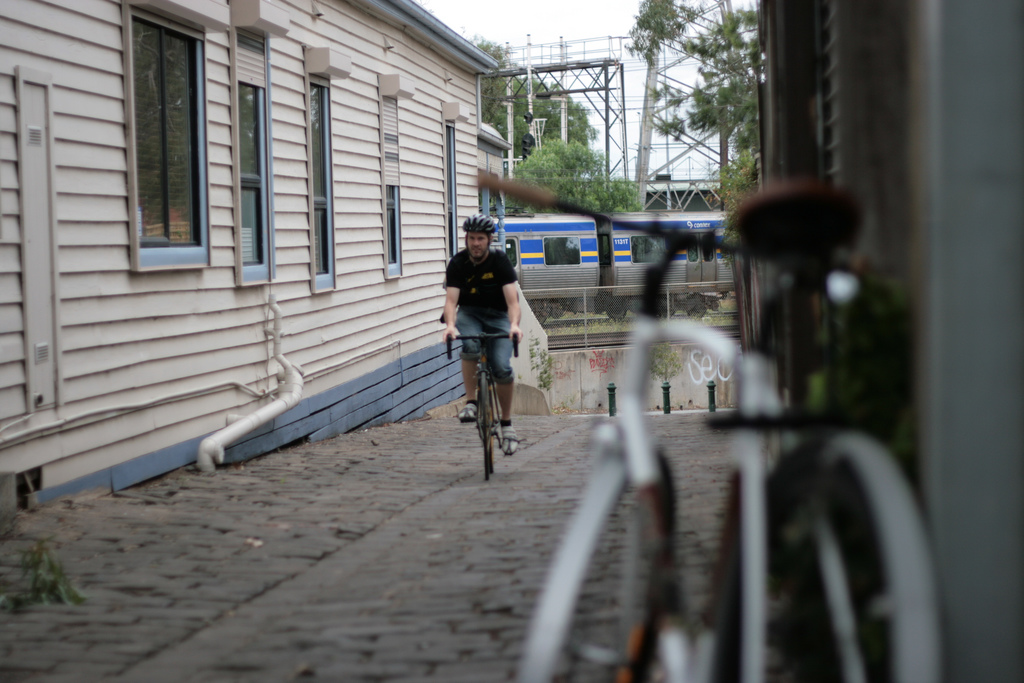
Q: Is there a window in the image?
A: Yes, there is a window.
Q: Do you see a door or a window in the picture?
A: Yes, there is a window.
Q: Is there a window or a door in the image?
A: Yes, there is a window.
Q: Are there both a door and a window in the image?
A: No, there is a window but no doors.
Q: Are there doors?
A: No, there are no doors.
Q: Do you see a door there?
A: No, there are no doors.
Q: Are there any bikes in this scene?
A: Yes, there is a bike.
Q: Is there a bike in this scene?
A: Yes, there is a bike.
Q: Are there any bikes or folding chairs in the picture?
A: Yes, there is a bike.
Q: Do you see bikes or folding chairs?
A: Yes, there is a bike.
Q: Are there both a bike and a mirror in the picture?
A: No, there is a bike but no mirrors.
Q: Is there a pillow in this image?
A: No, there are no pillows.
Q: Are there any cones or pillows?
A: No, there are no pillows or cones.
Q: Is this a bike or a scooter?
A: This is a bike.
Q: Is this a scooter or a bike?
A: This is a bike.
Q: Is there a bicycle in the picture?
A: Yes, there is a bicycle.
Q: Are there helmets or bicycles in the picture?
A: Yes, there is a bicycle.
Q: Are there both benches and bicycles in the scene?
A: No, there is a bicycle but no benches.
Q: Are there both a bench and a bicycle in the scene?
A: No, there is a bicycle but no benches.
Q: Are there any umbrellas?
A: No, there are no umbrellas.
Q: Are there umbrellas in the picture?
A: No, there are no umbrellas.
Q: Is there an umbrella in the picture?
A: No, there are no umbrellas.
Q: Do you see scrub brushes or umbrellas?
A: No, there are no umbrellas or scrub brushes.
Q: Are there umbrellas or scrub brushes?
A: No, there are no umbrellas or scrub brushes.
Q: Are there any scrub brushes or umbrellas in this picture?
A: No, there are no umbrellas or scrub brushes.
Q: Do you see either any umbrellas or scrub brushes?
A: No, there are no umbrellas or scrub brushes.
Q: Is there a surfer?
A: No, there are no surfers.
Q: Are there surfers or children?
A: No, there are no surfers or children.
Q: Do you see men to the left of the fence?
A: Yes, there is a man to the left of the fence.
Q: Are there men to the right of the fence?
A: No, the man is to the left of the fence.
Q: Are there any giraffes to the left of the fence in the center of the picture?
A: No, there is a man to the left of the fence.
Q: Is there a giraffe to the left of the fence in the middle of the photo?
A: No, there is a man to the left of the fence.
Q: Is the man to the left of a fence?
A: Yes, the man is to the left of a fence.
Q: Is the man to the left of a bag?
A: No, the man is to the left of a fence.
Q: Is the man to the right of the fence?
A: No, the man is to the left of the fence.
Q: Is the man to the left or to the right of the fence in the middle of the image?
A: The man is to the left of the fence.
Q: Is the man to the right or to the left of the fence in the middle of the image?
A: The man is to the left of the fence.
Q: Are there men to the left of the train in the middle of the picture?
A: Yes, there is a man to the left of the train.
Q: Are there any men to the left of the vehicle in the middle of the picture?
A: Yes, there is a man to the left of the train.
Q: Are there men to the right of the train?
A: No, the man is to the left of the train.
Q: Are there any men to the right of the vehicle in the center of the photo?
A: No, the man is to the left of the train.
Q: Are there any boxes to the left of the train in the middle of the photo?
A: No, there is a man to the left of the train.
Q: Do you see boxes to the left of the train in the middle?
A: No, there is a man to the left of the train.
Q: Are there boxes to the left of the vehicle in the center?
A: No, there is a man to the left of the train.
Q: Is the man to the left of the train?
A: Yes, the man is to the left of the train.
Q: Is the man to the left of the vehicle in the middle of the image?
A: Yes, the man is to the left of the train.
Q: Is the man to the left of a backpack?
A: No, the man is to the left of the train.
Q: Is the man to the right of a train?
A: No, the man is to the left of a train.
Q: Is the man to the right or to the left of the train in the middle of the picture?
A: The man is to the left of the train.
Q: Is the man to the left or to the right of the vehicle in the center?
A: The man is to the left of the train.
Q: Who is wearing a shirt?
A: The man is wearing a shirt.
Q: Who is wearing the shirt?
A: The man is wearing a shirt.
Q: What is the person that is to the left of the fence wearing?
A: The man is wearing a shirt.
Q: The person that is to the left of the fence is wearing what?
A: The man is wearing a shirt.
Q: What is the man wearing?
A: The man is wearing a shirt.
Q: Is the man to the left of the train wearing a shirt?
A: Yes, the man is wearing a shirt.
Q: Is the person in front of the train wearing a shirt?
A: Yes, the man is wearing a shirt.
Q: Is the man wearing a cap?
A: No, the man is wearing a shirt.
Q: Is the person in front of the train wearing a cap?
A: No, the man is wearing a shirt.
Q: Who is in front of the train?
A: The man is in front of the train.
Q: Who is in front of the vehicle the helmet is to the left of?
A: The man is in front of the train.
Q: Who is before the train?
A: The man is in front of the train.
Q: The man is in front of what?
A: The man is in front of the train.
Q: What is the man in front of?
A: The man is in front of the train.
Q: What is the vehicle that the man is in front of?
A: The vehicle is a train.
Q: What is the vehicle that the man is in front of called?
A: The vehicle is a train.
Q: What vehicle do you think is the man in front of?
A: The man is in front of the train.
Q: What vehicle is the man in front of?
A: The man is in front of the train.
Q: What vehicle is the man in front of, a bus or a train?
A: The man is in front of a train.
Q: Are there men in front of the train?
A: Yes, there is a man in front of the train.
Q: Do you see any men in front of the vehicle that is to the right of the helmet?
A: Yes, there is a man in front of the train.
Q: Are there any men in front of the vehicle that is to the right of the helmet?
A: Yes, there is a man in front of the train.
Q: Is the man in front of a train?
A: Yes, the man is in front of a train.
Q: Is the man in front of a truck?
A: No, the man is in front of a train.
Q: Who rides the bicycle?
A: The man rides the bicycle.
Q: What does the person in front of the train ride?
A: The man rides the bicycle.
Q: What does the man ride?
A: The man rides the bicycle.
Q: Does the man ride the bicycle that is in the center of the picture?
A: Yes, the man rides the bicycle.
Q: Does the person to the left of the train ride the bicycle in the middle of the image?
A: Yes, the man rides the bicycle.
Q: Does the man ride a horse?
A: No, the man rides the bicycle.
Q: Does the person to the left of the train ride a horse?
A: No, the man rides the bicycle.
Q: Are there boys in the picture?
A: No, there are no boys.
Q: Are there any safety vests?
A: No, there are no safety vests.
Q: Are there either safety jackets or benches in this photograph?
A: No, there are no safety jackets or benches.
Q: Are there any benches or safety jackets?
A: No, there are no safety jackets or benches.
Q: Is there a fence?
A: Yes, there is a fence.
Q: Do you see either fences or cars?
A: Yes, there is a fence.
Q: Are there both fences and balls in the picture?
A: No, there is a fence but no balls.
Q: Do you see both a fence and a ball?
A: No, there is a fence but no balls.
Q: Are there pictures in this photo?
A: No, there are no pictures.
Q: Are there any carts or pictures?
A: No, there are no pictures or carts.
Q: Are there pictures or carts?
A: No, there are no pictures or carts.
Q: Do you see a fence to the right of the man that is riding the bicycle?
A: Yes, there is a fence to the right of the man.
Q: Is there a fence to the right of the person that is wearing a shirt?
A: Yes, there is a fence to the right of the man.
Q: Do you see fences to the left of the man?
A: No, the fence is to the right of the man.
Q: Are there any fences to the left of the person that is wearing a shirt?
A: No, the fence is to the right of the man.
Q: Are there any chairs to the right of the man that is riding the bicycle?
A: No, there is a fence to the right of the man.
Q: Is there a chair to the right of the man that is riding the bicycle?
A: No, there is a fence to the right of the man.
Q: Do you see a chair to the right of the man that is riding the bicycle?
A: No, there is a fence to the right of the man.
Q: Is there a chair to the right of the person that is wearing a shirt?
A: No, there is a fence to the right of the man.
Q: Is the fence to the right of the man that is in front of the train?
A: Yes, the fence is to the right of the man.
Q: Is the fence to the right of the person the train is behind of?
A: Yes, the fence is to the right of the man.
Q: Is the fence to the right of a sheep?
A: No, the fence is to the right of the man.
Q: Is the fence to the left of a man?
A: No, the fence is to the right of a man.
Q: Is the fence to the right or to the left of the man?
A: The fence is to the right of the man.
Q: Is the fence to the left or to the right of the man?
A: The fence is to the right of the man.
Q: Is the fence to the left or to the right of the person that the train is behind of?
A: The fence is to the right of the man.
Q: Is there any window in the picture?
A: Yes, there are windows.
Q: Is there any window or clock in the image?
A: Yes, there are windows.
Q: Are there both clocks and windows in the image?
A: No, there are windows but no clocks.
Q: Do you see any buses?
A: No, there are no buses.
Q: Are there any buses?
A: No, there are no buses.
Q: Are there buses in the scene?
A: No, there are no buses.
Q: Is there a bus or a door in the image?
A: No, there are no buses or doors.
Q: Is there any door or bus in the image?
A: No, there are no buses or doors.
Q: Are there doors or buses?
A: No, there are no buses or doors.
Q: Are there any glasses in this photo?
A: No, there are no glasses.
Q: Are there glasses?
A: No, there are no glasses.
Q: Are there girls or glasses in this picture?
A: No, there are no glasses or girls.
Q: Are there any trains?
A: Yes, there is a train.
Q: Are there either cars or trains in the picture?
A: Yes, there is a train.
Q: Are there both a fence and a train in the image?
A: Yes, there are both a train and a fence.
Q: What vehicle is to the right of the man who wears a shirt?
A: The vehicle is a train.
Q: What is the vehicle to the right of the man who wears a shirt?
A: The vehicle is a train.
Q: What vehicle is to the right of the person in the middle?
A: The vehicle is a train.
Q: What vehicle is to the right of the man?
A: The vehicle is a train.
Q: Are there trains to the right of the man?
A: Yes, there is a train to the right of the man.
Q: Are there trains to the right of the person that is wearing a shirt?
A: Yes, there is a train to the right of the man.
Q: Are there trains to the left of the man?
A: No, the train is to the right of the man.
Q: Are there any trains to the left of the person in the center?
A: No, the train is to the right of the man.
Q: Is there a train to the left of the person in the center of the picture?
A: No, the train is to the right of the man.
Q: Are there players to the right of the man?
A: No, there is a train to the right of the man.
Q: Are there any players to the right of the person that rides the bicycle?
A: No, there is a train to the right of the man.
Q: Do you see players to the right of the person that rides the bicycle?
A: No, there is a train to the right of the man.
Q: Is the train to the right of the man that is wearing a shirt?
A: Yes, the train is to the right of the man.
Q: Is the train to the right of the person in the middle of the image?
A: Yes, the train is to the right of the man.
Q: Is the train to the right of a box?
A: No, the train is to the right of the man.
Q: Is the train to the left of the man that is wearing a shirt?
A: No, the train is to the right of the man.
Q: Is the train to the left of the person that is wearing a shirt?
A: No, the train is to the right of the man.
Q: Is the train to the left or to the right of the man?
A: The train is to the right of the man.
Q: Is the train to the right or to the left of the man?
A: The train is to the right of the man.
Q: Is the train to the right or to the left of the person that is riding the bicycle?
A: The train is to the right of the man.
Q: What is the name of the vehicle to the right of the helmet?
A: The vehicle is a train.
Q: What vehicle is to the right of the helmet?
A: The vehicle is a train.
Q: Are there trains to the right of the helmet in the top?
A: Yes, there is a train to the right of the helmet.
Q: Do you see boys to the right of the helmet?
A: No, there is a train to the right of the helmet.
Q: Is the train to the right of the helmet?
A: Yes, the train is to the right of the helmet.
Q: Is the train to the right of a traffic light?
A: No, the train is to the right of the helmet.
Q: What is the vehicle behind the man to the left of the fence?
A: The vehicle is a train.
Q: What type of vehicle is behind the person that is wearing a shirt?
A: The vehicle is a train.